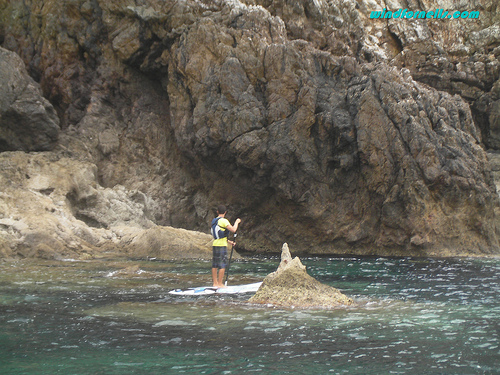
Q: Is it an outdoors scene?
A: Yes, it is outdoors.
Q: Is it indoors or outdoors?
A: It is outdoors.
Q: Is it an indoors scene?
A: No, it is outdoors.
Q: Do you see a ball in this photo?
A: No, there are no balls.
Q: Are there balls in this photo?
A: No, there are no balls.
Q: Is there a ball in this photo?
A: No, there are no balls.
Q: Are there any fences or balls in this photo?
A: No, there are no balls or fences.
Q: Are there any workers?
A: No, there are no workers.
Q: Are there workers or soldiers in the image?
A: No, there are no workers or soldiers.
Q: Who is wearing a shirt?
A: The boy is wearing a shirt.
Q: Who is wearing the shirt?
A: The boy is wearing a shirt.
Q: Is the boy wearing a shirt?
A: Yes, the boy is wearing a shirt.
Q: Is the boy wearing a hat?
A: No, the boy is wearing a shirt.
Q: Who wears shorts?
A: The boy wears shorts.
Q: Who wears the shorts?
A: The boy wears shorts.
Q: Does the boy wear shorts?
A: Yes, the boy wears shorts.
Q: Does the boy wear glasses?
A: No, the boy wears shorts.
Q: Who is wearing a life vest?
A: The boy is wearing a life vest.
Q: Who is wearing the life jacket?
A: The boy is wearing a life vest.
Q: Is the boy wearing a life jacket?
A: Yes, the boy is wearing a life jacket.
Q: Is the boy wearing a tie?
A: No, the boy is wearing a life jacket.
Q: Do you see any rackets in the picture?
A: No, there are no rackets.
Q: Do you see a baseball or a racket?
A: No, there are no rackets or baseballs.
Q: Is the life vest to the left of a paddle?
A: Yes, the life vest is to the left of a paddle.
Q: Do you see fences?
A: No, there are no fences.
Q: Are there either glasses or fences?
A: No, there are no fences or glasses.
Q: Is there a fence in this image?
A: No, there are no fences.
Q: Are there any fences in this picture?
A: No, there are no fences.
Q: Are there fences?
A: No, there are no fences.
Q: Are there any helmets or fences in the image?
A: No, there are no fences or helmets.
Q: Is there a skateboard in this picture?
A: No, there are no skateboards.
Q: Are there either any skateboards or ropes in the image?
A: No, there are no skateboards or ropes.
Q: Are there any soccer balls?
A: No, there are no soccer balls.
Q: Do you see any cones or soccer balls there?
A: No, there are no soccer balls or cones.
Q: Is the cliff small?
A: Yes, the cliff is small.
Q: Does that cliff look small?
A: Yes, the cliff is small.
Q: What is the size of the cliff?
A: The cliff is small.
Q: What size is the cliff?
A: The cliff is small.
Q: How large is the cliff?
A: The cliff is small.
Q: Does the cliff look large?
A: No, the cliff is small.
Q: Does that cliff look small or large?
A: The cliff is small.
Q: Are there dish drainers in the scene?
A: No, there are no dish drainers.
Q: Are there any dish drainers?
A: No, there are no dish drainers.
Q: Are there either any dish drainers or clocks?
A: No, there are no dish drainers or clocks.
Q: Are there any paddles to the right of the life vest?
A: Yes, there is a paddle to the right of the life vest.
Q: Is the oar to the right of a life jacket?
A: Yes, the oar is to the right of a life jacket.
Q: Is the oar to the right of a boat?
A: No, the oar is to the right of a life jacket.